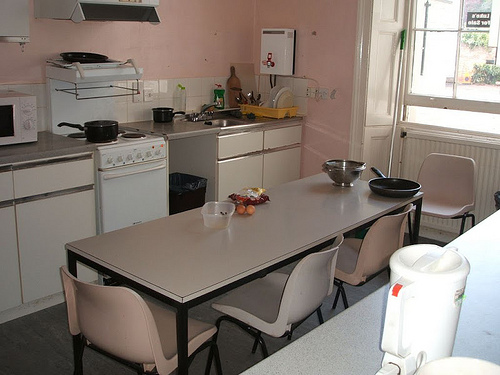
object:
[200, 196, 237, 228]
container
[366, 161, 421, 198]
pan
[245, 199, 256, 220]
orange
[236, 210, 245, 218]
orange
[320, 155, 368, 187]
bowl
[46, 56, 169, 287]
range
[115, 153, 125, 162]
knobs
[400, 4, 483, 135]
window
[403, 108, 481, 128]
open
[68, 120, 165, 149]
stove top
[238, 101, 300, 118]
drainer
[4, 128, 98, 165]
counter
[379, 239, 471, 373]
pitcher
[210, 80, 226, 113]
bottle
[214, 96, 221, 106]
detergent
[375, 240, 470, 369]
kettle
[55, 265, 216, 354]
chairs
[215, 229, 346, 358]
chairs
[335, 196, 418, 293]
chairs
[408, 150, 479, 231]
chairs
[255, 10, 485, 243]
wall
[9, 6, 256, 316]
wall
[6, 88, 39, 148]
microwave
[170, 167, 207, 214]
can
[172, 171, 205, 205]
liner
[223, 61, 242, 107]
board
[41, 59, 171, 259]
stove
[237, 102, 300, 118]
rack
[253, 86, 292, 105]
dishes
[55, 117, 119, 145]
pan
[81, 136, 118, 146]
burner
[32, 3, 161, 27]
vent